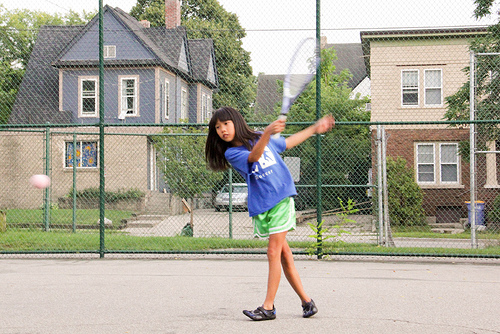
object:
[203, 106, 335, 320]
girl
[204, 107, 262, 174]
hair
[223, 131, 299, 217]
shirt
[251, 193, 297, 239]
shorts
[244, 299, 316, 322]
shoes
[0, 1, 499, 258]
fence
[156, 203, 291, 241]
driveway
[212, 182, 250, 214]
car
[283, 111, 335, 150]
skin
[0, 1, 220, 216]
house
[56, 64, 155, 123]
wall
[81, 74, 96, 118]
window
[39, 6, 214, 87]
roof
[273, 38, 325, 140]
racket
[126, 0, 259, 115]
tree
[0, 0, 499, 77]
sky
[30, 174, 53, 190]
tennis ball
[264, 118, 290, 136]
hand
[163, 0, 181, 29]
chimney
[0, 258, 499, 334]
floor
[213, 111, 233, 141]
face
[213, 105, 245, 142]
head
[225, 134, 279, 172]
arm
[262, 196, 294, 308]
leg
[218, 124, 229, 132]
nose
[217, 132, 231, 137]
mouth